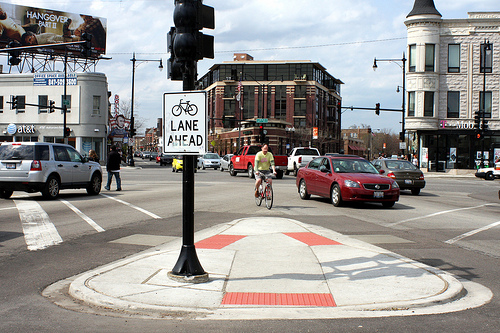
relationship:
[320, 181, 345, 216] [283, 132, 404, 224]
tire of car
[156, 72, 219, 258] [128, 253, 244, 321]
pole on ground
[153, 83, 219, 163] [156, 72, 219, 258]
sign on pole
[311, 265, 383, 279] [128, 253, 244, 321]
shadow on ground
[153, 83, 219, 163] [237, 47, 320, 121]
sign on building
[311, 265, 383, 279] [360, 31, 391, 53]
shadow from sun